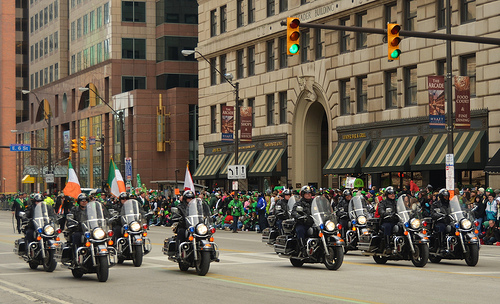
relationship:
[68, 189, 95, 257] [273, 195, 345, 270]
person on motorcycle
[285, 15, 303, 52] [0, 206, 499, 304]
traffic light above road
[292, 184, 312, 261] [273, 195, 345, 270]
man riding motorcycle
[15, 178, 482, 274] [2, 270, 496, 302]
motorbikes on road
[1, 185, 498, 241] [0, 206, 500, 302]
crowd along street